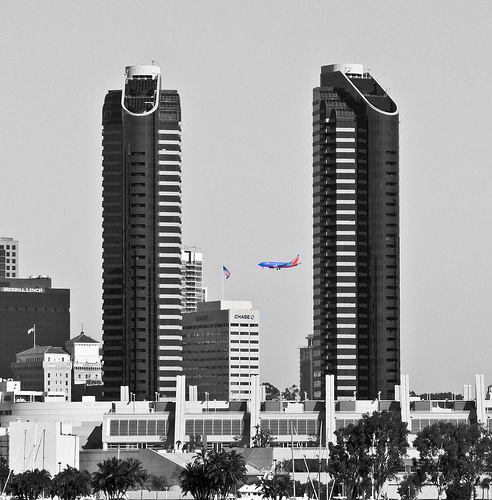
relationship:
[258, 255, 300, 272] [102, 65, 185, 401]
airplane between tower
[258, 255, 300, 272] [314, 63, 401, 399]
airplane between tower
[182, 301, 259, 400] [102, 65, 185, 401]
building between tower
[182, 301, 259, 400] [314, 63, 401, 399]
building between tower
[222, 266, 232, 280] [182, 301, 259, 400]
flag on top of building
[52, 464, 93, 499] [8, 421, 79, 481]
tree in front of building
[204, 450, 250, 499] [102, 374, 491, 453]
tree in front of building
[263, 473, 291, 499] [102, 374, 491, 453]
tree in front of building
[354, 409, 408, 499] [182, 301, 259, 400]
tree in front of building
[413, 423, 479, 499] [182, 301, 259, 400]
tree in front of building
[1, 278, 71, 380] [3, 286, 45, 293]
building with label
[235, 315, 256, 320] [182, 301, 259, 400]
logo on top of building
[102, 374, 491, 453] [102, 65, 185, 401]
building in front of tower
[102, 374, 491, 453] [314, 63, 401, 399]
building in front of tower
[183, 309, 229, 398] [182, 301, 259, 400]
side of building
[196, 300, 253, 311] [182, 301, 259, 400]
part of building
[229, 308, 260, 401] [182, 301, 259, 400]
edge of building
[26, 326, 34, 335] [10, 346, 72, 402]
flag on top of building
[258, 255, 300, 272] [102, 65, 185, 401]
airplane seen between tower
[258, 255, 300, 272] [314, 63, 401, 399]
airplane seen between tower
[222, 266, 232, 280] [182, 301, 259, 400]
flag atop building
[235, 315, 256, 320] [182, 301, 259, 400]
logo displayed on building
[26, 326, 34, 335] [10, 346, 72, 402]
flag atop building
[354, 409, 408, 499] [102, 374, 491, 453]
tree in front of building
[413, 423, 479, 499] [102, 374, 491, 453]
tree in front of building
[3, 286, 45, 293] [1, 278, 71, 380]
label displayed on building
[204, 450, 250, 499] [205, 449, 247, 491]
tree has leaves